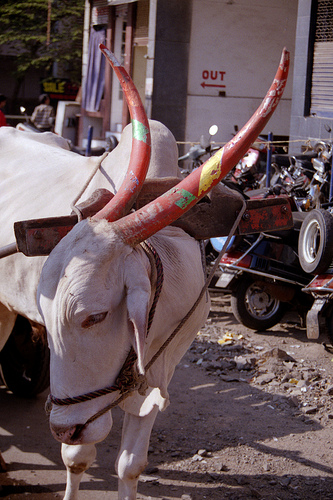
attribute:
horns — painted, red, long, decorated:
[97, 41, 332, 231]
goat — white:
[1, 129, 210, 497]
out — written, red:
[200, 68, 230, 83]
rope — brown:
[121, 241, 171, 389]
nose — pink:
[49, 422, 82, 449]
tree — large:
[11, 5, 56, 106]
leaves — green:
[4, 4, 37, 23]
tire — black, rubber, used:
[295, 208, 331, 280]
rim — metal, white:
[305, 222, 321, 262]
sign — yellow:
[43, 78, 71, 95]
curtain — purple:
[316, 12, 332, 102]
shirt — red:
[2, 115, 8, 127]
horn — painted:
[163, 52, 305, 240]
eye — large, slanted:
[82, 311, 108, 325]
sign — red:
[201, 67, 229, 93]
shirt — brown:
[37, 108, 55, 131]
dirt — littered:
[215, 347, 328, 420]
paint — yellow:
[202, 155, 222, 189]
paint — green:
[170, 193, 195, 209]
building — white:
[198, 2, 298, 143]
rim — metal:
[248, 287, 273, 315]